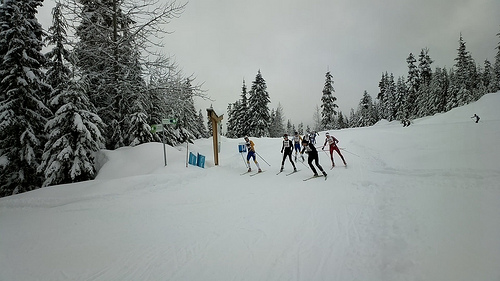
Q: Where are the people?
A: Skiing.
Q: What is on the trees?
A: Snow.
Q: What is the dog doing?
A: No dog.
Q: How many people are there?
A: Ten.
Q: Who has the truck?
A: No truck.